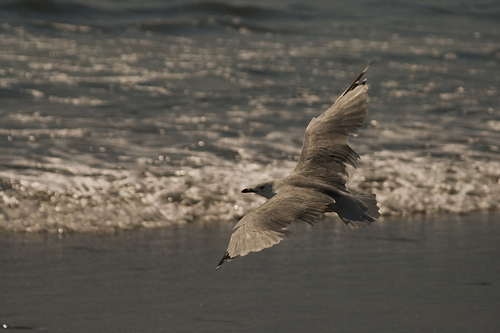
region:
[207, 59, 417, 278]
bird that is flying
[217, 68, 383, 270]
wings are oustretched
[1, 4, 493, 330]
bird flying over the beach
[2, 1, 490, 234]
body of water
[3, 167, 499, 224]
water rolling into the shore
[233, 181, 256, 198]
small pointed beak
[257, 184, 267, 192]
small eye on the side of the head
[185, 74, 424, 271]
large white bird in flight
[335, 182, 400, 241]
feathers on the tail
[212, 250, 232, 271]
tip of the wing is black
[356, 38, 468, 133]
ripples on the water surface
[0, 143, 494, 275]
wave on the beach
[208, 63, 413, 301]
bird in the air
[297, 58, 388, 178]
wing of the bird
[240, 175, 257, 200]
beck of the bird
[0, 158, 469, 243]
foam of the water hitting the shore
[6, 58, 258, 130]
wave in the water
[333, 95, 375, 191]
feathers on the birds wing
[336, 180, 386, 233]
tail of the bird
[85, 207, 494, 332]
sand on the shore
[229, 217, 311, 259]
the birds wing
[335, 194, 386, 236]
the birds tail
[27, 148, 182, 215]
the water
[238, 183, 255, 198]
the birds beak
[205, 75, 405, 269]
the bird is flying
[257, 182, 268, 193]
the birds eye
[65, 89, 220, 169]
the ocean water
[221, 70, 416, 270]
the bird is grey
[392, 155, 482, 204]
water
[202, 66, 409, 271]
the bird is in the air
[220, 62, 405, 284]
Bird soaring over water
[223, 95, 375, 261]
white bird flying over water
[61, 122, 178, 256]
waves crashing in the water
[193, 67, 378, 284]
bird with its wings expanded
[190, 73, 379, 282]
bird that is flying south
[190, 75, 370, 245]
bird soaring over water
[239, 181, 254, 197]
black beack on a seagull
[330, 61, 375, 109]
black feathers on the tip of wings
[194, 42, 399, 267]
flying grey and white seagull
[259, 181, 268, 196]
black eye of a seagull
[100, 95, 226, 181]
sun glinting off of the ocean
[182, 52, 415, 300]
seagull flying at the beach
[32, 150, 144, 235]
waves crashing on the shore line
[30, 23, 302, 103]
grey and blue ocean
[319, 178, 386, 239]
grey tail feathers of a seagull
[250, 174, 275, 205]
white face of a sea gull